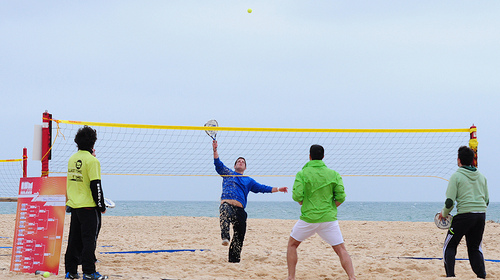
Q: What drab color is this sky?
A: Grey.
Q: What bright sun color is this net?
A: Yellow.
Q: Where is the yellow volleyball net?
A: On the beach.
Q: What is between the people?
A: Yellow net.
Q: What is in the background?
A: The ocean.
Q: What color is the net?
A: Yellow.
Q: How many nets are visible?
A: Two.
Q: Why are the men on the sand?
A: Playing volleyball.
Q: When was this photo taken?
A: Daytime.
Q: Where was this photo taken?
A: Beach.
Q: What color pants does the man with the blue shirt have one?
A: Black.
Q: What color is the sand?
A: Tan.